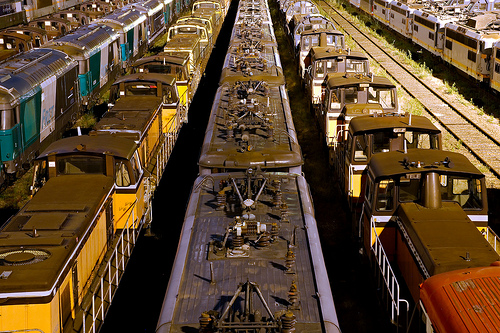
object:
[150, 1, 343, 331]
trains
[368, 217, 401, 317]
ladder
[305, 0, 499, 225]
grass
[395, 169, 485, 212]
window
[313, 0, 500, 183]
rail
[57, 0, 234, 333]
fence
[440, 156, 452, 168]
bolt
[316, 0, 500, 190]
ground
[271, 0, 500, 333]
train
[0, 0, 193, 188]
train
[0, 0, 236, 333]
train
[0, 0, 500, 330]
yard